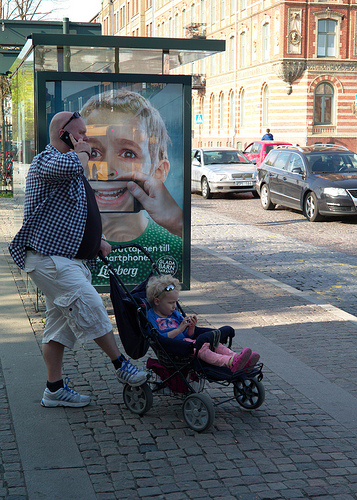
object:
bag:
[109, 272, 153, 361]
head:
[49, 111, 88, 150]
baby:
[146, 273, 261, 381]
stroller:
[100, 242, 266, 431]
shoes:
[115, 356, 152, 388]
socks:
[47, 378, 65, 392]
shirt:
[146, 308, 194, 344]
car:
[255, 144, 357, 222]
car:
[192, 147, 260, 199]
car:
[238, 139, 292, 172]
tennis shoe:
[40, 377, 90, 408]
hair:
[146, 272, 180, 301]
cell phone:
[59, 130, 78, 149]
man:
[22, 111, 149, 407]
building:
[82, 0, 357, 168]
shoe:
[230, 347, 252, 372]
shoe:
[242, 351, 260, 373]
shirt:
[8, 144, 88, 270]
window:
[317, 18, 338, 59]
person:
[261, 128, 273, 141]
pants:
[183, 337, 236, 368]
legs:
[188, 339, 231, 369]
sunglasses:
[155, 283, 175, 299]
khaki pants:
[23, 249, 112, 351]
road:
[190, 192, 357, 318]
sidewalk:
[0, 185, 357, 500]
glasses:
[62, 111, 82, 130]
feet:
[40, 377, 92, 407]